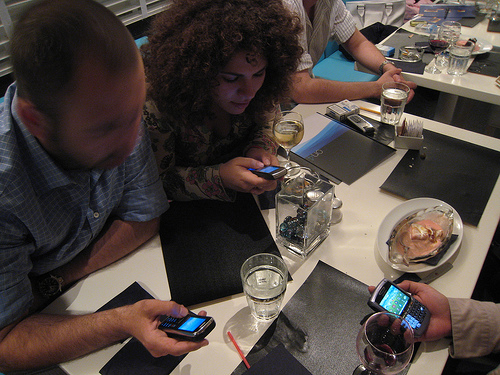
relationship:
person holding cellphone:
[351, 186, 484, 357] [371, 277, 442, 336]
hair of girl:
[130, 0, 306, 128] [144, 6, 304, 207]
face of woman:
[224, 60, 261, 114] [136, 0, 304, 205]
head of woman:
[205, 31, 275, 113] [136, 0, 304, 205]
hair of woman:
[150, 4, 290, 124] [136, 0, 304, 205]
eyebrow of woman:
[254, 63, 272, 74] [136, 0, 304, 205]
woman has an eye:
[136, 0, 304, 205] [205, 63, 248, 93]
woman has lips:
[96, 0, 360, 223] [97, 0, 338, 236]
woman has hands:
[136, 0, 304, 205] [190, 140, 330, 200]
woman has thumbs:
[136, 0, 304, 205] [219, 144, 324, 171]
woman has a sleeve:
[136, 0, 304, 205] [134, 160, 223, 209]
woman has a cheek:
[136, 0, 304, 205] [196, 79, 240, 114]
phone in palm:
[365, 277, 430, 339] [344, 276, 485, 355]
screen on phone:
[373, 276, 417, 327] [347, 272, 452, 340]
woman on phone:
[136, 0, 304, 205] [249, 140, 300, 200]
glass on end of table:
[239, 252, 287, 322] [167, 41, 479, 372]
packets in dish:
[392, 114, 435, 154] [374, 118, 431, 161]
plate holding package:
[373, 197, 463, 272] [370, 106, 428, 156]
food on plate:
[381, 177, 477, 288] [363, 150, 488, 286]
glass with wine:
[239, 252, 287, 322] [276, 119, 302, 143]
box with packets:
[393, 117, 430, 147] [403, 116, 425, 135]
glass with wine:
[239, 252, 287, 322] [356, 332, 406, 372]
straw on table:
[228, 330, 259, 373] [19, 97, 491, 371]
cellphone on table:
[343, 110, 376, 137] [19, 97, 491, 371]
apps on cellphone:
[379, 285, 409, 317] [367, 276, 429, 334]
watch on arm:
[377, 53, 392, 72] [330, 0, 413, 95]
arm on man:
[330, 0, 413, 95] [280, 1, 414, 104]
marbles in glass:
[280, 204, 328, 246] [276, 171, 330, 258]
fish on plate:
[383, 201, 457, 262] [378, 196, 462, 273]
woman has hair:
[136, 0, 304, 205] [140, 1, 303, 142]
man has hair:
[0, 2, 210, 362] [7, 1, 140, 152]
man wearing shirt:
[0, 2, 210, 362] [1, 80, 164, 322]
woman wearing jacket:
[136, 0, 304, 205] [138, 68, 283, 199]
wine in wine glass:
[276, 120, 304, 150] [272, 109, 302, 174]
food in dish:
[392, 218, 445, 260] [384, 200, 456, 265]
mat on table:
[230, 259, 419, 372] [19, 97, 491, 371]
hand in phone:
[217, 155, 277, 195] [248, 163, 286, 179]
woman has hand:
[136, 0, 304, 205] [217, 155, 277, 195]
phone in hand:
[369, 279, 431, 342] [366, 278, 451, 338]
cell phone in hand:
[160, 312, 215, 342] [129, 298, 209, 356]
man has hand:
[0, 2, 210, 362] [129, 298, 209, 356]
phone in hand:
[365, 277, 430, 339] [368, 280, 453, 343]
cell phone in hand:
[241, 157, 287, 179] [218, 153, 274, 195]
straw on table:
[225, 328, 251, 369] [19, 97, 491, 371]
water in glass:
[245, 264, 282, 318] [354, 309, 417, 375]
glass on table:
[354, 309, 417, 375] [19, 97, 491, 371]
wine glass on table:
[277, 107, 304, 170] [19, 97, 491, 371]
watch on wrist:
[42, 274, 62, 294] [40, 274, 63, 298]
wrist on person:
[40, 274, 63, 298] [1, 1, 208, 359]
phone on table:
[365, 277, 430, 339] [19, 97, 491, 371]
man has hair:
[0, 0, 210, 375] [140, 1, 303, 142]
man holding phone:
[0, 0, 210, 375] [257, 159, 277, 178]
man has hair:
[0, 0, 210, 375] [56, 31, 94, 51]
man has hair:
[0, 0, 210, 375] [52, 19, 101, 53]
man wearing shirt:
[0, 0, 210, 375] [11, 156, 123, 261]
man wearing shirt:
[0, 0, 210, 375] [19, 166, 127, 247]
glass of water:
[234, 250, 299, 343] [251, 263, 276, 284]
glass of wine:
[272, 106, 306, 156] [278, 127, 295, 144]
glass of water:
[239, 252, 287, 322] [381, 101, 401, 120]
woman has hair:
[136, 0, 304, 205] [190, 15, 236, 52]